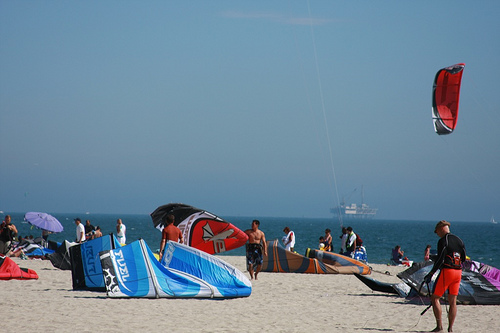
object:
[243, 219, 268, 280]
man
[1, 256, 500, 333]
beach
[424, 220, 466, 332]
man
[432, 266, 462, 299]
shorts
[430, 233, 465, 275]
tee shirt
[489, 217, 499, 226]
boat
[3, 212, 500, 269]
ocean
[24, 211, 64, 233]
umbrella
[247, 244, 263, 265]
shorts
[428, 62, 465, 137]
kite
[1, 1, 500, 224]
sky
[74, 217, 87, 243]
man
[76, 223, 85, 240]
tee shirt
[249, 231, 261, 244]
chest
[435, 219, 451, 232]
cap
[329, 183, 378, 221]
oil rig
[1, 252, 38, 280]
kite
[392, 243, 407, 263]
person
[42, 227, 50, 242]
person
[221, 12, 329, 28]
cloud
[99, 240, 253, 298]
kite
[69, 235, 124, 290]
kite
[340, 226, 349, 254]
man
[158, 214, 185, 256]
man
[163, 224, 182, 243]
tee shirt